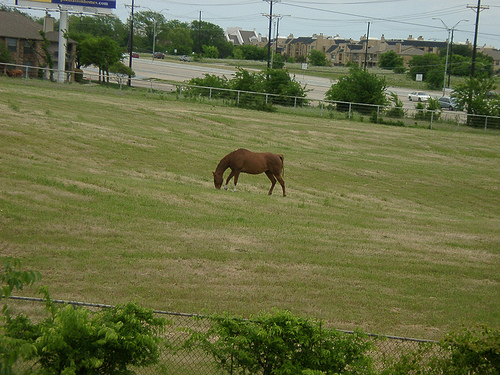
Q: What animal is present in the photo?
A: A horse.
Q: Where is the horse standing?
A: In the grass.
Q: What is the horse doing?
A: Grazing.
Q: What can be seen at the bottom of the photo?
A: A fence.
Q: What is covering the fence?
A: Plants.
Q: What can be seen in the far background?
A: Buildings.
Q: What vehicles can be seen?
A: Cars.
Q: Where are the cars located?
A: On the road.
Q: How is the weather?
A: Cloudy.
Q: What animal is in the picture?
A: A horse.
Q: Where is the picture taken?
A: A field.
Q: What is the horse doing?
A: Grazing.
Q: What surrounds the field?
A: A fence.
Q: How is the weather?
A: Sunny.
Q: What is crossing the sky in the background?
A: Electrical wires.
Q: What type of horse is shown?
A: Brown.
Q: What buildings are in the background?
A: Apartments.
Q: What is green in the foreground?
A: Bushes.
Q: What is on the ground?
A: Grass.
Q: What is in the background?
A: Buildings.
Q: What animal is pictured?
A: A horse.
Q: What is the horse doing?
A: Eating.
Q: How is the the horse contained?
A: A fence.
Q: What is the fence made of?
A: Wire.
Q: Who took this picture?
A: A pedestrian.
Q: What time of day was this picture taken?
A: Afternoon.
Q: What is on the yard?
A: A horse.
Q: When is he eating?
A: Now.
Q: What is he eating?
A: Grass.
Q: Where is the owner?
A: In the house.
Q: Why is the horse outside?
A: To run the open fields.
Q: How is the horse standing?
A: On 4 legs.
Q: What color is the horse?
A: Brown.